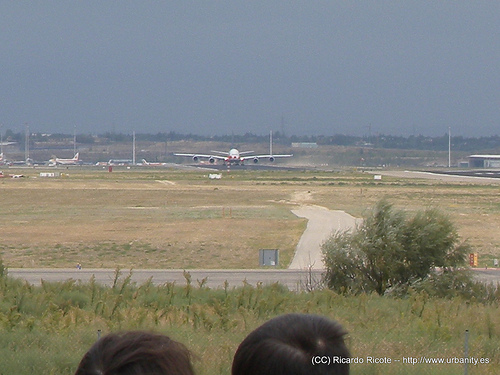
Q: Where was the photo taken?
A: Near an airport.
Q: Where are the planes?
A: On the runway.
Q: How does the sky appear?
A: Blue and hazy.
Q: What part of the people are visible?
A: Back of heads.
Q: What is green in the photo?
A: Grass and bush.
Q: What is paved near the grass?
A: A road.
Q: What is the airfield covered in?
A: Brown grass.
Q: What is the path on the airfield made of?
A: Sand.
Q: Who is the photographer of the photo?
A: Ricardo Ricote.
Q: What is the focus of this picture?
A: A part of a road.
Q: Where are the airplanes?
A: Air strip.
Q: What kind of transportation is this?
A: Airplane.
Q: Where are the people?
A: In front of the camera.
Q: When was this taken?
A: Daytime.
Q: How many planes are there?
A: 2.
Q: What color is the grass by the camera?
A: Green.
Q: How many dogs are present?
A: None.